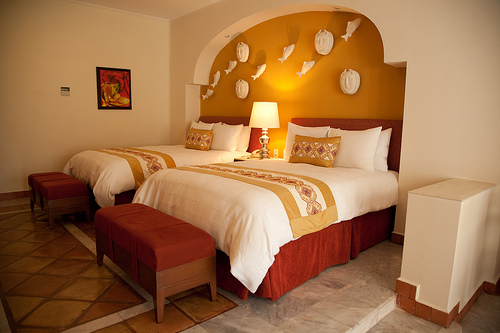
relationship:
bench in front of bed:
[19, 171, 213, 314] [65, 122, 393, 316]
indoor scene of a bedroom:
[16, 21, 489, 314] [3, 3, 468, 329]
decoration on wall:
[192, 8, 409, 118] [169, 1, 498, 227]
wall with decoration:
[169, 1, 498, 227] [192, 8, 409, 118]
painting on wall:
[94, 65, 136, 112] [5, 6, 177, 182]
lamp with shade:
[249, 99, 280, 159] [248, 103, 285, 129]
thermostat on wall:
[57, 85, 77, 101] [5, 6, 177, 182]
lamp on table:
[249, 99, 280, 159] [227, 147, 273, 166]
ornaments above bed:
[192, 8, 409, 118] [69, 115, 393, 262]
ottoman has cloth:
[94, 203, 217, 324] [97, 195, 209, 269]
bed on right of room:
[69, 115, 393, 262] [13, 120, 475, 332]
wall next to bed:
[169, 1, 498, 227] [357, 161, 434, 275]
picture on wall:
[94, 65, 136, 112] [5, 6, 177, 182]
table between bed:
[227, 147, 273, 166] [69, 115, 393, 262]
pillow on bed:
[287, 136, 339, 167] [69, 115, 393, 262]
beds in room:
[69, 115, 393, 262] [3, 1, 495, 245]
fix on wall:
[192, 8, 409, 118] [169, 1, 498, 227]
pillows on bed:
[282, 120, 386, 176] [196, 112, 408, 296]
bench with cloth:
[19, 171, 213, 314] [94, 203, 216, 272]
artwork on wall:
[94, 65, 136, 112] [5, 6, 177, 182]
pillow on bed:
[282, 120, 386, 176] [69, 115, 393, 262]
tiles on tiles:
[247, 254, 412, 331] [0, 191, 500, 332]